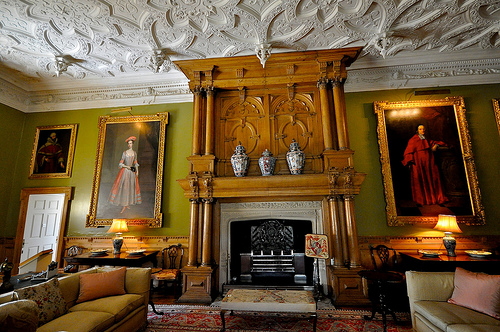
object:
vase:
[285, 138, 305, 174]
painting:
[84, 112, 168, 229]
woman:
[107, 136, 142, 214]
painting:
[373, 96, 485, 226]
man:
[401, 124, 447, 207]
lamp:
[433, 214, 463, 256]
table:
[399, 252, 497, 273]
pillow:
[448, 267, 500, 319]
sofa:
[405, 270, 500, 331]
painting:
[27, 123, 78, 179]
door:
[11, 187, 73, 277]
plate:
[464, 250, 492, 258]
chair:
[357, 245, 405, 332]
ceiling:
[0, 0, 499, 85]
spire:
[255, 43, 275, 68]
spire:
[374, 31, 395, 59]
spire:
[149, 50, 164, 73]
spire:
[51, 56, 73, 77]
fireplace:
[219, 201, 328, 295]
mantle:
[176, 173, 367, 198]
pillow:
[76, 266, 126, 302]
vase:
[258, 148, 275, 176]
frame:
[149, 112, 170, 228]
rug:
[146, 304, 415, 331]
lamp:
[106, 218, 129, 255]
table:
[63, 250, 160, 268]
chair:
[150, 244, 183, 299]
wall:
[0, 50, 500, 238]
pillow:
[0, 258, 39, 300]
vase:
[230, 141, 250, 177]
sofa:
[0, 266, 152, 332]